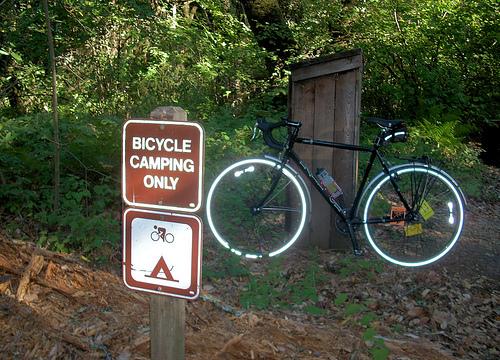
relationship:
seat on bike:
[353, 112, 443, 147] [205, 123, 467, 269]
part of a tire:
[356, 216, 466, 268] [357, 163, 468, 269]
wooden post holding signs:
[147, 106, 187, 359] [121, 119, 202, 213]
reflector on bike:
[231, 164, 255, 177] [211, 94, 498, 295]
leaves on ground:
[404, 297, 486, 351] [229, 258, 498, 358]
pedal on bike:
[347, 242, 366, 261] [259, 115, 425, 245]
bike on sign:
[150, 227, 178, 252] [106, 112, 214, 314]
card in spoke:
[405, 222, 422, 236] [411, 239, 427, 259]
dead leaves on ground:
[350, 272, 498, 345] [1, 156, 496, 356]